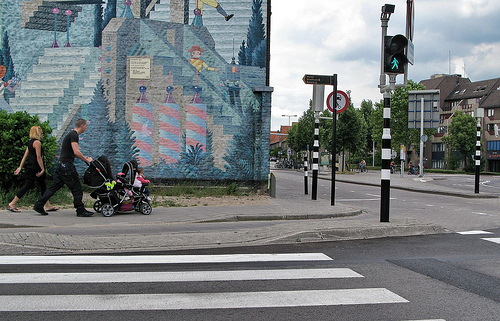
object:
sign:
[326, 90, 349, 113]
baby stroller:
[83, 155, 153, 217]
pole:
[311, 84, 325, 200]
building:
[412, 74, 499, 175]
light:
[384, 34, 409, 74]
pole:
[380, 93, 392, 222]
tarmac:
[0, 223, 499, 320]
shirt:
[58, 130, 80, 163]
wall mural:
[0, 0, 272, 180]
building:
[0, 0, 274, 196]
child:
[133, 168, 152, 201]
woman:
[6, 126, 60, 213]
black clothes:
[16, 139, 46, 200]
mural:
[0, 0, 269, 181]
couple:
[6, 119, 95, 218]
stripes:
[1, 250, 446, 321]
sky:
[269, 0, 500, 132]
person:
[391, 57, 400, 69]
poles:
[380, 93, 392, 222]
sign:
[407, 39, 415, 65]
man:
[33, 118, 95, 218]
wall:
[0, 0, 270, 195]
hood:
[82, 155, 115, 187]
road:
[0, 228, 499, 321]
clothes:
[15, 139, 46, 199]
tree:
[0, 106, 61, 199]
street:
[0, 161, 499, 320]